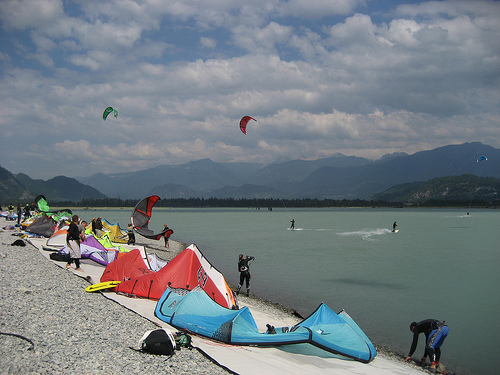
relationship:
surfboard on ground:
[86, 275, 130, 300] [68, 282, 84, 316]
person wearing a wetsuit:
[283, 209, 300, 238] [290, 221, 295, 228]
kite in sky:
[238, 115, 258, 136] [230, 13, 314, 70]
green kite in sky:
[96, 101, 129, 129] [230, 13, 314, 70]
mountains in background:
[156, 154, 492, 195] [270, 138, 321, 157]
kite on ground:
[139, 278, 390, 364] [68, 282, 84, 316]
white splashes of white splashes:
[348, 226, 384, 244] [335, 227, 391, 241]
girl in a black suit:
[236, 254, 256, 297] [235, 258, 252, 287]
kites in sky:
[84, 89, 497, 202] [230, 13, 314, 70]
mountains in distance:
[156, 154, 492, 195] [312, 121, 404, 143]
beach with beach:
[2, 220, 85, 373] [0, 194, 499, 375]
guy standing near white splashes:
[403, 307, 453, 361] [335, 227, 391, 241]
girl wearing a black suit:
[231, 249, 257, 297] [236, 257, 256, 297]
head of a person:
[233, 252, 251, 260] [283, 209, 300, 238]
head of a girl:
[233, 252, 251, 260] [236, 254, 256, 297]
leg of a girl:
[244, 272, 255, 298] [236, 254, 256, 297]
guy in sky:
[403, 318, 450, 372] [230, 13, 314, 70]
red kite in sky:
[229, 110, 270, 140] [230, 13, 314, 70]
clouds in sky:
[221, 26, 357, 100] [230, 13, 314, 70]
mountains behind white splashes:
[156, 154, 492, 195] [335, 227, 391, 241]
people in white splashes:
[249, 190, 476, 268] [335, 227, 391, 241]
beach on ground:
[0, 194, 499, 375] [68, 282, 84, 316]